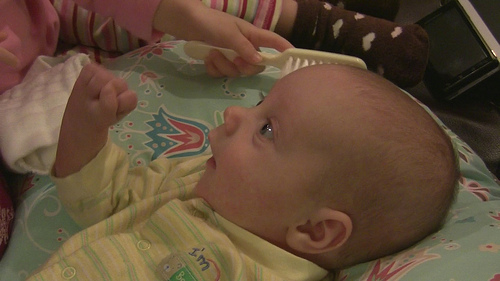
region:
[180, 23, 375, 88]
The brush is white.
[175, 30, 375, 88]
The brush is on the baby's head.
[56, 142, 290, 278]
The pajamas are yellow.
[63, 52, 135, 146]
The hand is up.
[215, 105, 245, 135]
a baby's nose.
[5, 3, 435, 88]
The child is holding a brush.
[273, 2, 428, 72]
Her sock is brown.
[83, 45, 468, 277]
The pillow is blue.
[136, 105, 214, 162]
The flower is blue.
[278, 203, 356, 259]
a baby's ear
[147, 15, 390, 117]
a kid is brushing baby's hair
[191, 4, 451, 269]
a kid is brushing baby's hair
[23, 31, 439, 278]
the onesie is yellow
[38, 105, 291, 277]
the onesie is yellow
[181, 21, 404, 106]
the brush is white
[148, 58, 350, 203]
the baby is looking up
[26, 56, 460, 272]
This is a baby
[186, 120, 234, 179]
The baby's mouth is open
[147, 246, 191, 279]
There is a bear on the baby's clothes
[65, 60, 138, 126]
The baby is making a fist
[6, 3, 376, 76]
A person is combing the baby's hair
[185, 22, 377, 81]
The comb is white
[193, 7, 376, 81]
The comb is in the person's left hand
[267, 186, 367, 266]
The baby's left ear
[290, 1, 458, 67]
These socks have hearts on them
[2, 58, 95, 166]
Small white towel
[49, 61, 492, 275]
baby in a yellow onsie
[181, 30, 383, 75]
white plastic comb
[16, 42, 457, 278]
baby on a green pillow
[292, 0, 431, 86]
brown sock with pink hearts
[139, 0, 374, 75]
hand holding a comb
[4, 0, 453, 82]
child wearing pink clothing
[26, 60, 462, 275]
baby laying on his back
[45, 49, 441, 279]
baby with blue eyes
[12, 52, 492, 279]
infant making a fist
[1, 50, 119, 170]
white infant blanket